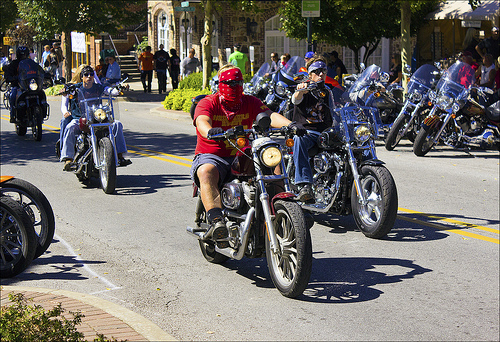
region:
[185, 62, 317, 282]
biker is wearing red mask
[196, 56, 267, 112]
man wearing red bandana over face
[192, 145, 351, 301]
red motorcycle with light on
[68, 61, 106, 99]
man wearing black helmet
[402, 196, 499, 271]
yellow line painted down city street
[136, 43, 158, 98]
adult wearing orange shirt walking down street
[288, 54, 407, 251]
man driving motorcycle down street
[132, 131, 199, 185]
yellow double line painted on street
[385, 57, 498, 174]
motorcycles parked on street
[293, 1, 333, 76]
green and white sign on street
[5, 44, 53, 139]
motorcycle with light on driving down street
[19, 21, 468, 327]
some people on motorcycles.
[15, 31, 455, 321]
several people on motorcycles.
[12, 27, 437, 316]
group of people on motorcycles.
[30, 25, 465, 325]
people riding motorcycles during daytime.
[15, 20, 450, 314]
several people riding motorcycles during daytime.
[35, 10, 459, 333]
group of people riding motorcycles during daytime.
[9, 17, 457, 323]
multiple people riding motorcycles during daytime.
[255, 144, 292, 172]
headlight of a motorcycle.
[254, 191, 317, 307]
front wheel of a motorcycle.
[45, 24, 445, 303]
people riding motorcycles down the street.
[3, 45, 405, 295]
men riding motorcycles down a street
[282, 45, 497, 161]
motorcycles parked on the side of the street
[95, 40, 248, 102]
people walking on the sidewalk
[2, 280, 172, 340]
the curb is lined with red bricks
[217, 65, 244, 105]
the man is wearing a red bandana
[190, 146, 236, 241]
the man is wearing gray shorts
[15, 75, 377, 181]
the motorcycles' headlights are on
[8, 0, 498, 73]
green trees are by the street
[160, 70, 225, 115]
green bushes are on the street corner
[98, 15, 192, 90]
steps lead up the front of the building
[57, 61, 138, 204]
biker wearing blue on blue bike